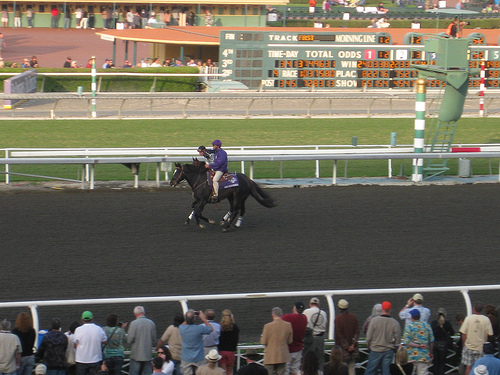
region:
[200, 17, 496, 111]
a green score board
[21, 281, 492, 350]
a white metal fence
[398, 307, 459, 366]
someone wearing a flowered shirt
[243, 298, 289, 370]
a man wearing a tan jacket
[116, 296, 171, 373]
a man with white hair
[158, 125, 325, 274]
a man riding a brown horse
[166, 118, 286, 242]
a man riding a horse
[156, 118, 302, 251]
two men riding horses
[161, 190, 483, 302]
a dirt track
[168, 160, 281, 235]
a black horse on the race track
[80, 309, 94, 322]
a green cap on a man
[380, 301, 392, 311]
a red cap on a man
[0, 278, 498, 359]
a white barricade at the horse track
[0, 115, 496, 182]
green grass inside the track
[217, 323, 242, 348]
a black shirt on a woman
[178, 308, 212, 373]
a man taking a picture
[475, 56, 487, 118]
a red and white striped post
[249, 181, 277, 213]
a black tail on a horse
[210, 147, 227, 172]
a blue shirt on a woman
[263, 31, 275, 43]
The letter is white.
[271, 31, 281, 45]
The letter is white.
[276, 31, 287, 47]
The letter is white.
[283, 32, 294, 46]
The letter is white.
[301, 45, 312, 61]
The letter is white.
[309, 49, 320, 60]
The letter is white.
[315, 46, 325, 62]
The letter is white.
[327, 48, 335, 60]
The letter is white.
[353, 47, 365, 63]
The letter is white.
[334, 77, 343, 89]
The letter is white.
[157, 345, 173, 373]
Woman wearing sun glasses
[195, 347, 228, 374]
Man wearing a beige shirt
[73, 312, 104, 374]
Man wearing a green cap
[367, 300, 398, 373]
Man wearing a red cap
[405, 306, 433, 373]
Man wearing a multi-colored shirt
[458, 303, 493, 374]
Man wearing plaid shorts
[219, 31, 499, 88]
A scoreboard at a horse race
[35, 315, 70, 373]
A man wearing a gray and black hoodie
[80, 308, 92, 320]
A green hat worn on a head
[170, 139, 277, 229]
A horse gliding along on a track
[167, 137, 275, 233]
a man on a racehorse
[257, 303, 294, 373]
an older gentleman in tan coat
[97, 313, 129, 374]
a woman wearing a cross body bag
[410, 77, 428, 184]
a green and white pole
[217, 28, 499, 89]
a scoreboard with numbers on it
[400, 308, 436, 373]
a woman in a flowered shirt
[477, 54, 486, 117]
a red and white pole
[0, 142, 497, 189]
a metal fence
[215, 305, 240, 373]
a woman with a ponytail